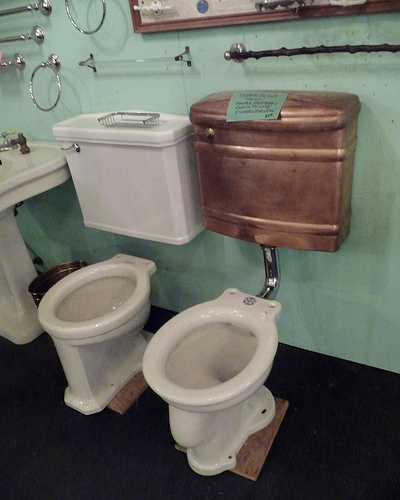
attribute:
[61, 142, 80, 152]
handle — silver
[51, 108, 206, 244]
water tank — white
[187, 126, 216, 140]
handle — bronze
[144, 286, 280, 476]
toilet — white, porcelain 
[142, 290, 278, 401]
lid — white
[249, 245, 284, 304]
frame — silver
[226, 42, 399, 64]
towel rod — black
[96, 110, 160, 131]
tray — silver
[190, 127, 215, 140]
handle — gold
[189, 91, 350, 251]
water tank — gold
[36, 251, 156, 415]
toilet — porcelain , white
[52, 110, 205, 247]
tank — white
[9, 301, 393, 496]
floor — black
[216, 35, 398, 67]
rack — black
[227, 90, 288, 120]
paper — green, small piece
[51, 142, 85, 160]
handle — silver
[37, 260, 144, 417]
tank — toliet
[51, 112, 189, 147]
lid — white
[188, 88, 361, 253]
tank — gold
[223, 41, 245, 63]
handle — silver